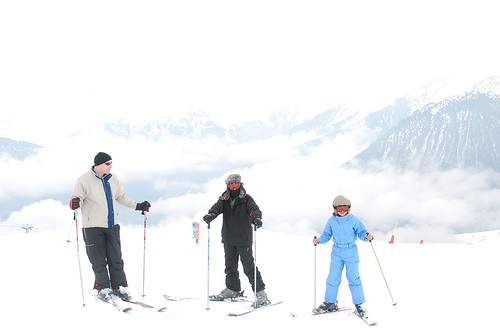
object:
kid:
[311, 193, 375, 317]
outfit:
[316, 212, 370, 307]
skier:
[202, 173, 272, 309]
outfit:
[207, 187, 267, 293]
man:
[68, 150, 154, 306]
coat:
[70, 164, 138, 229]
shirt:
[92, 172, 114, 228]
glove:
[69, 197, 81, 211]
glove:
[135, 200, 152, 212]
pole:
[74, 208, 87, 308]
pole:
[141, 210, 149, 299]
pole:
[312, 235, 318, 311]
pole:
[365, 232, 397, 307]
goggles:
[334, 204, 350, 212]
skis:
[289, 306, 352, 319]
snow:
[89, 74, 466, 125]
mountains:
[0, 135, 49, 161]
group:
[68, 150, 375, 319]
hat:
[94, 151, 112, 166]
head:
[93, 151, 113, 175]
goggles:
[227, 183, 240, 190]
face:
[227, 182, 241, 193]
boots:
[207, 287, 240, 302]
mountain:
[339, 75, 499, 174]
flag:
[192, 222, 200, 244]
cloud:
[150, 156, 500, 241]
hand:
[68, 196, 81, 211]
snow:
[0, 231, 500, 334]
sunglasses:
[104, 160, 113, 166]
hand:
[135, 200, 152, 213]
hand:
[312, 237, 320, 246]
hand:
[365, 233, 373, 240]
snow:
[411, 72, 498, 112]